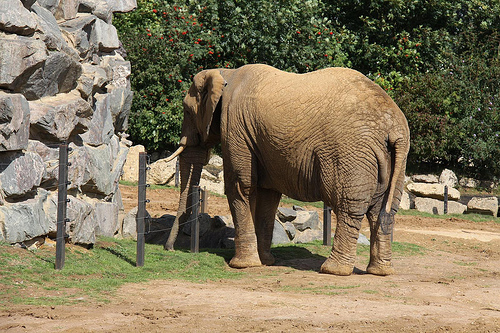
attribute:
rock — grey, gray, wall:
[1, 2, 500, 248]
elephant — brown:
[166, 58, 413, 289]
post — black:
[55, 145, 200, 265]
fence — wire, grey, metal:
[2, 140, 334, 283]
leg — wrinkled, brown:
[226, 175, 400, 277]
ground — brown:
[13, 177, 500, 331]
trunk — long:
[161, 154, 204, 251]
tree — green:
[123, 3, 500, 189]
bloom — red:
[140, 3, 227, 77]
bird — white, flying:
[120, 70, 129, 85]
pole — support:
[136, 152, 147, 264]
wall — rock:
[1, 0, 137, 250]